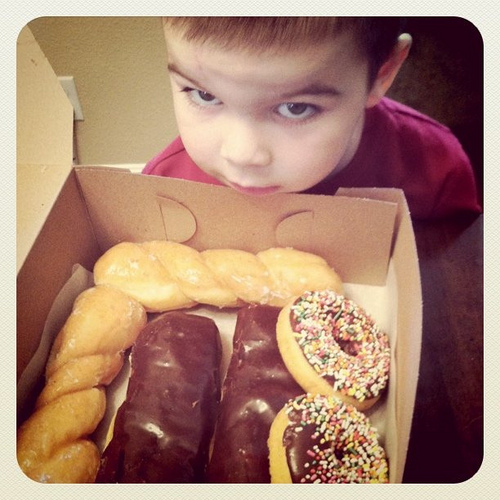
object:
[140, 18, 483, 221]
child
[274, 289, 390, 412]
donut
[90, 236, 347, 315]
pastry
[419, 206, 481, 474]
table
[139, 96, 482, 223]
shirt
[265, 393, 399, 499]
donuts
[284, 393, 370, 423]
sprinkles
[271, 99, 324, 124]
eyes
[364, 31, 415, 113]
ear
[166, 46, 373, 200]
face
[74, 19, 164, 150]
wall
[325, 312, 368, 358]
hole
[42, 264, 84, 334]
paper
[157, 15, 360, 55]
brown hair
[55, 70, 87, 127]
outlet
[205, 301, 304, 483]
eclair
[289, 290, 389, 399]
chocolate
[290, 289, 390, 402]
sprinkles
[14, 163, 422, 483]
box